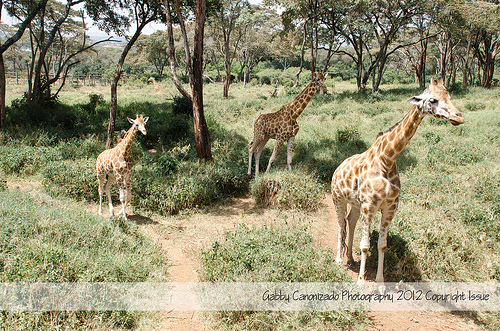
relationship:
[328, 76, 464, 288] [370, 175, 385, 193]
giraffe has spot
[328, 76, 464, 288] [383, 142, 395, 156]
giraffe has spot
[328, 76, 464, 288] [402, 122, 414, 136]
giraffe has spot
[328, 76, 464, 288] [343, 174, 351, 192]
giraffe has spot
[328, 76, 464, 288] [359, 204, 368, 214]
giraffe has spot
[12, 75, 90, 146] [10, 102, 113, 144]
tree has shadow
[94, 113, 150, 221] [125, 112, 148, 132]
giraffe has head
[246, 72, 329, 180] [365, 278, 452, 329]
giraffe leading way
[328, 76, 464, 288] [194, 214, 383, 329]
giraffe walking near shrubs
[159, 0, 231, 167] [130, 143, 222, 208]
tree surrounded by shrub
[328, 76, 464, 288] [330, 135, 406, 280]
giraffe has orange markings body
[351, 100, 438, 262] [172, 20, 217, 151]
giraffe near tree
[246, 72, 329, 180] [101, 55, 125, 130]
giraffe near tree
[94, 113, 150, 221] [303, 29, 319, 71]
giraffe near tree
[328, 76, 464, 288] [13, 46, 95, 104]
giraffe in sun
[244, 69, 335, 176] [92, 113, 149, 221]
giraffe in giraffe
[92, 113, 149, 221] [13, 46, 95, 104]
giraffe in sun